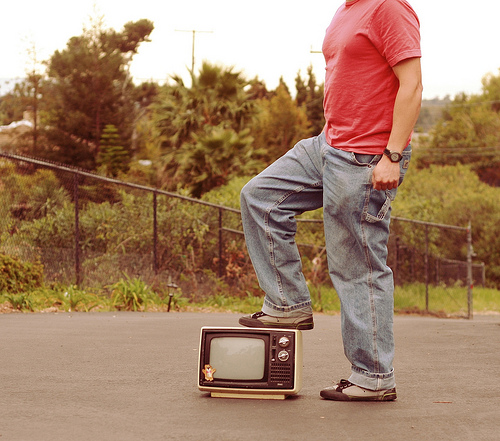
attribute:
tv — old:
[189, 319, 310, 409]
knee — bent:
[240, 181, 297, 224]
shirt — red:
[316, 12, 411, 152]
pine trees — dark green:
[18, 2, 152, 199]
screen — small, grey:
[189, 313, 304, 405]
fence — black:
[14, 140, 480, 335]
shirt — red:
[317, 1, 422, 157]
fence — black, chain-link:
[46, 162, 188, 290]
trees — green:
[34, 22, 272, 152]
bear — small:
[201, 364, 216, 381]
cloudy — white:
[155, 4, 296, 92]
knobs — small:
[275, 333, 292, 363]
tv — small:
[189, 292, 304, 416]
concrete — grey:
[4, 307, 498, 439]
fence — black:
[1, 143, 492, 320]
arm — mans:
[375, 9, 425, 201]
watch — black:
[388, 145, 398, 161]